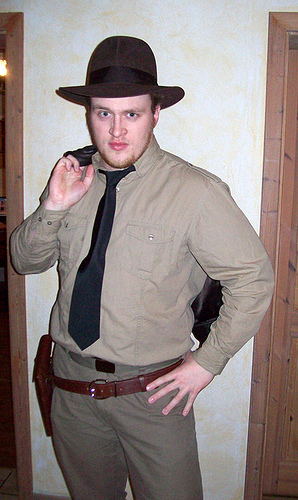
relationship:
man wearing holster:
[9, 35, 275, 498] [32, 333, 55, 438]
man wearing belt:
[9, 35, 275, 498] [49, 358, 185, 400]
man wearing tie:
[9, 35, 275, 498] [67, 165, 136, 351]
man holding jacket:
[9, 35, 275, 498] [63, 145, 222, 348]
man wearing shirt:
[9, 35, 275, 498] [8, 132, 276, 374]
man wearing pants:
[9, 35, 275, 498] [49, 343, 204, 499]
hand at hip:
[146, 351, 217, 416] [133, 353, 195, 419]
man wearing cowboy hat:
[9, 35, 275, 498] [58, 35, 185, 111]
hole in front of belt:
[117, 386, 124, 393] [49, 358, 185, 400]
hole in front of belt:
[109, 388, 114, 394] [49, 358, 185, 400]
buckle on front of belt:
[87, 377, 111, 400] [49, 358, 185, 400]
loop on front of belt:
[136, 373, 148, 392] [49, 358, 185, 400]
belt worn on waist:
[49, 358, 185, 400] [48, 336, 189, 384]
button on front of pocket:
[147, 233, 155, 243] [119, 223, 176, 282]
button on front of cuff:
[46, 219, 53, 226] [28, 198, 70, 234]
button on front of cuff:
[37, 215, 42, 223] [28, 198, 70, 234]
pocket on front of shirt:
[119, 223, 176, 282] [8, 132, 276, 374]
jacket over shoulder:
[63, 145, 222, 348] [43, 147, 103, 185]